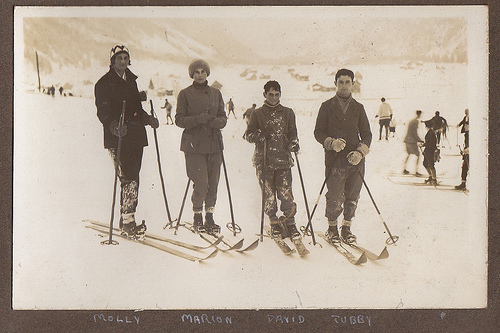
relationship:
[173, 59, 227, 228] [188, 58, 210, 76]
woman has hat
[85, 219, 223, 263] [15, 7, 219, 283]
skiis on left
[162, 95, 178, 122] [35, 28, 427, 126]
person in distance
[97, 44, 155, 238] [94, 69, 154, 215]
person in skii gear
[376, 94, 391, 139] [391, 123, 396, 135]
person with toddler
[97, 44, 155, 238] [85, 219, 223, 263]
person with skiis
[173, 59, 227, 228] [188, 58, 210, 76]
woman wearing hat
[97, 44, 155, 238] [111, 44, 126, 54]
person wearing hat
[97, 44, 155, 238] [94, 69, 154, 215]
person wearing dark clothes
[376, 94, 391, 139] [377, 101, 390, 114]
person has top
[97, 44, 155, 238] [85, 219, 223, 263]
person on skiis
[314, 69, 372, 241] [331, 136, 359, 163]
boy has gloves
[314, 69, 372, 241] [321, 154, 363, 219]
kid has pants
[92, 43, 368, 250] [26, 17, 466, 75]
family in front of mountain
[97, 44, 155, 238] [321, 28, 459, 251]
person leaning right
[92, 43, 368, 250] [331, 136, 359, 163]
family wearing gloves